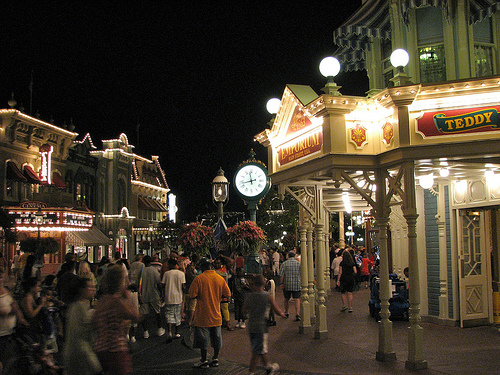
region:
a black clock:
[188, 138, 314, 269]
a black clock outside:
[214, 137, 294, 237]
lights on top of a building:
[283, 40, 436, 131]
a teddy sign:
[398, 98, 495, 152]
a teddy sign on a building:
[394, 88, 496, 155]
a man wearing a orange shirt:
[178, 255, 242, 361]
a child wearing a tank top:
[236, 273, 284, 351]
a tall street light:
[198, 158, 263, 260]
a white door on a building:
[440, 188, 499, 345]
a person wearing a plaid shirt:
[267, 248, 300, 314]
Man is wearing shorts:
[190, 320, 226, 350]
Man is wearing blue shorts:
[191, 322, 226, 352]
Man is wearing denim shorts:
[189, 319, 226, 350]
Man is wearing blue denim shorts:
[188, 321, 223, 349]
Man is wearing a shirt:
[184, 268, 233, 327]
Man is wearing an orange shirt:
[185, 266, 231, 327]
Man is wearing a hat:
[192, 252, 217, 264]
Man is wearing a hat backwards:
[195, 252, 215, 262]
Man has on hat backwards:
[190, 250, 210, 260]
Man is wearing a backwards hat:
[185, 251, 215, 263]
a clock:
[232, 167, 272, 197]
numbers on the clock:
[250, 178, 264, 191]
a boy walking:
[231, 285, 286, 348]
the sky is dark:
[58, 30, 253, 116]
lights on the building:
[310, 52, 359, 81]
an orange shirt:
[192, 277, 237, 324]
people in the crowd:
[130, 263, 202, 310]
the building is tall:
[6, 133, 191, 253]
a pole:
[376, 265, 411, 315]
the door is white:
[457, 231, 495, 325]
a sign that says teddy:
[405, 96, 495, 144]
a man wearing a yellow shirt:
[183, 243, 244, 338]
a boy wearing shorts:
[239, 248, 331, 360]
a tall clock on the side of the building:
[223, 145, 288, 216]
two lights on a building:
[300, 23, 454, 99]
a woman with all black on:
[333, 223, 377, 310]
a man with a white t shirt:
[154, 249, 199, 311]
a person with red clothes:
[76, 252, 184, 367]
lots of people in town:
[97, 191, 282, 354]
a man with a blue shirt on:
[268, 243, 325, 296]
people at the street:
[58, 220, 183, 343]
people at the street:
[136, 206, 248, 333]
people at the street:
[188, 178, 285, 335]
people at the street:
[50, 228, 135, 318]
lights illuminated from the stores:
[236, 92, 326, 161]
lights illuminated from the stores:
[246, 75, 458, 190]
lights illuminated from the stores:
[37, 133, 124, 246]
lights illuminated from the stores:
[102, 145, 174, 181]